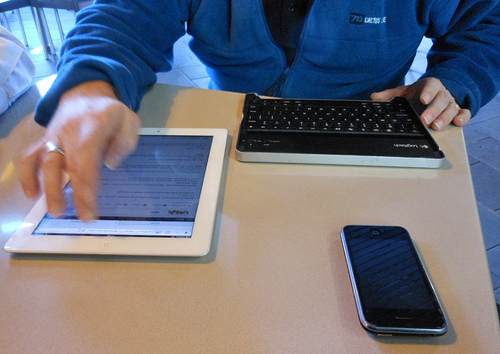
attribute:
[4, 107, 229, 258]
ipad — white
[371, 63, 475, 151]
hand — person's, resting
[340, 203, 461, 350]
iphone — black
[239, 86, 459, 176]
tablet keyboard — black, wireless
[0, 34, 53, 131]
bag — white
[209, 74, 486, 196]
keyboard — black, silver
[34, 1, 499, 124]
blue jacket — fleece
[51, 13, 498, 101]
jacket — person's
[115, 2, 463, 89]
shirt — blue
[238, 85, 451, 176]
keyboard — black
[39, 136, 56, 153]
ring — silver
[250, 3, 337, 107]
zipper — blue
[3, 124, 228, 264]
tablet — white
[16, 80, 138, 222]
hand — person's, touching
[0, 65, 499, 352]
table — brown, shiny, light brown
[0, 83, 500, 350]
desk — wooden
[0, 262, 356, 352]
table top — tan colored top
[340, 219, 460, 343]
cellphone — silver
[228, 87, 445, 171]
keyboard — black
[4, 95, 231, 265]
woman/white tablet — white